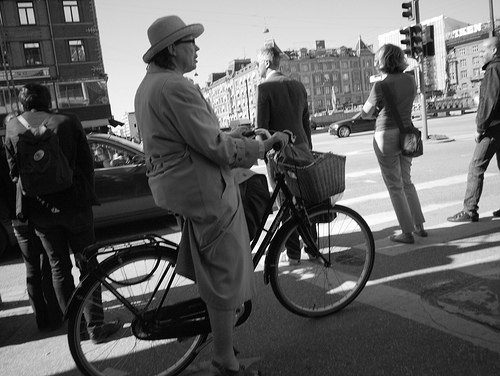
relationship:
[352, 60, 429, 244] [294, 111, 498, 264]
woman on street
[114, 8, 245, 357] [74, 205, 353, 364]
woman on bike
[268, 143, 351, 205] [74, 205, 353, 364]
basket on bike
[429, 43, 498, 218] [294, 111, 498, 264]
man on street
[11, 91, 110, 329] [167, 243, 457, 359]
man on sidewalk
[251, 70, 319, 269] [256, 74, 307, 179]
man wears suit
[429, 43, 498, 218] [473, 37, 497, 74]
man has head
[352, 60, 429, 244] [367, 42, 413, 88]
woman has head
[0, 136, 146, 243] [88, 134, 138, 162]
car has window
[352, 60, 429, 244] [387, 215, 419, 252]
woman has foot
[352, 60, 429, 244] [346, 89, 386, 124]
woman has arm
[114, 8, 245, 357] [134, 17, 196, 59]
woman has hat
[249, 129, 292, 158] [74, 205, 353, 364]
handlebars on bike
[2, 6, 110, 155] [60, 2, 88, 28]
building has window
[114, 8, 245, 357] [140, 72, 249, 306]
woman wears coat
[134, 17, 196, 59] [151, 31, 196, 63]
hat has brim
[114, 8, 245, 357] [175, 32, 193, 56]
woman wears glasses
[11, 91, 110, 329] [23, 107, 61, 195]
man wears backpack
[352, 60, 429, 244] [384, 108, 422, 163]
woman wears purse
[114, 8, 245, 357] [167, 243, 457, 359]
woman waits on sidewalk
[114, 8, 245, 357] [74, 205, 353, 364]
woman stands on bike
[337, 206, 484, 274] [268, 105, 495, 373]
shadows cast on ground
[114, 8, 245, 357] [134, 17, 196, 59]
woman wears hat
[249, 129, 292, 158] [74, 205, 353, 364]
handlebars on front of bike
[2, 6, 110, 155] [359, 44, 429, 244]
building away from woman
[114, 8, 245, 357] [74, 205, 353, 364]
woman rides bike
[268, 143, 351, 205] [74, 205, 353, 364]
basket in front of bike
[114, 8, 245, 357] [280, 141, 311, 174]
woman carries bag